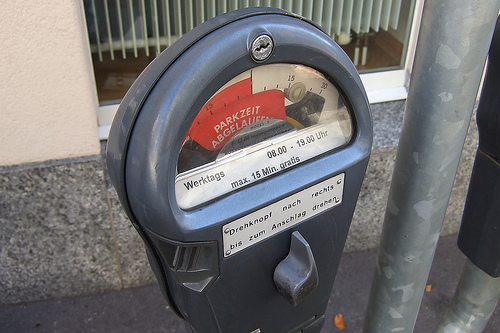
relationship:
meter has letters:
[98, 18, 417, 319] [220, 186, 344, 217]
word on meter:
[182, 170, 226, 193] [104, 7, 376, 331]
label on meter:
[182, 76, 289, 161] [104, 7, 376, 331]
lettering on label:
[212, 106, 273, 150] [186, 76, 286, 155]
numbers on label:
[192, 87, 253, 127] [182, 76, 289, 161]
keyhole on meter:
[251, 34, 273, 60] [104, 7, 376, 331]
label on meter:
[221, 174, 347, 259] [104, 7, 376, 331]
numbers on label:
[252, 125, 336, 177] [175, 115, 345, 207]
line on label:
[250, 69, 253, 95] [181, 55, 292, 152]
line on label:
[192, 118, 200, 128] [181, 55, 292, 152]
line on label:
[205, 110, 215, 120] [181, 55, 292, 152]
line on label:
[235, 92, 247, 106] [181, 55, 292, 152]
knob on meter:
[271, 224, 324, 321] [105, 5, 372, 333]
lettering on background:
[202, 100, 267, 150] [182, 79, 292, 153]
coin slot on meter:
[165, 240, 210, 278] [105, 5, 372, 333]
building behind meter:
[0, 0, 494, 304] [105, 5, 372, 333]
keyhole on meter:
[254, 32, 273, 62] [105, 5, 372, 333]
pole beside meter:
[361, 2, 497, 330] [105, 5, 372, 333]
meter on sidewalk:
[105, 5, 372, 333] [0, 95, 500, 329]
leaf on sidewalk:
[331, 308, 350, 330] [0, 95, 500, 329]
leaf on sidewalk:
[425, 279, 434, 295] [0, 95, 500, 329]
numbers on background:
[246, 150, 306, 180] [173, 117, 353, 212]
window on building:
[82, 0, 416, 110] [1, 0, 491, 169]